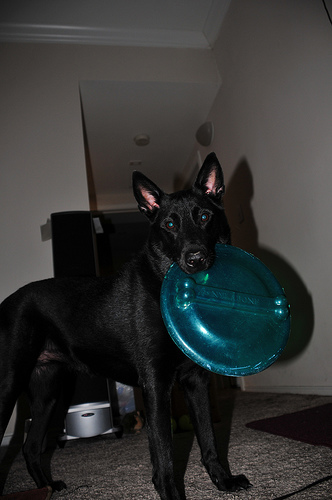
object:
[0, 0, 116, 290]
walls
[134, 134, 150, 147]
fire alarm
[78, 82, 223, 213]
ceiling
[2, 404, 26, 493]
tail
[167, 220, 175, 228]
eyes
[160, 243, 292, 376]
frisbee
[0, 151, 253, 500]
black dog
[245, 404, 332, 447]
carpet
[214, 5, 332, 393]
wall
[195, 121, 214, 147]
light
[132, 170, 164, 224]
ear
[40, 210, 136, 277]
speaker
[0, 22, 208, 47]
molding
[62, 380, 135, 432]
shelf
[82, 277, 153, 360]
black fur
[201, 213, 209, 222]
eye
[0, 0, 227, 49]
ceiling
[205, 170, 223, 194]
pink skin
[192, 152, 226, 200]
dog's ear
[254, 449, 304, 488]
carpet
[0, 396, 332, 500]
floor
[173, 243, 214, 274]
dog's mouth